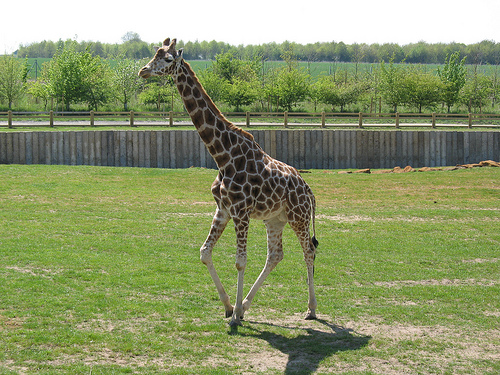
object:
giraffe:
[135, 36, 320, 328]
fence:
[0, 109, 499, 129]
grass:
[0, 161, 499, 374]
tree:
[41, 44, 102, 115]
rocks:
[460, 158, 497, 169]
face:
[137, 51, 174, 78]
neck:
[180, 70, 238, 158]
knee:
[198, 246, 214, 267]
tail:
[306, 185, 319, 250]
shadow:
[226, 303, 375, 375]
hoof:
[301, 307, 318, 322]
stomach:
[254, 204, 287, 223]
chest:
[218, 171, 253, 207]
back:
[241, 130, 304, 188]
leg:
[295, 221, 319, 322]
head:
[137, 36, 185, 81]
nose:
[138, 66, 150, 73]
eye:
[164, 54, 175, 63]